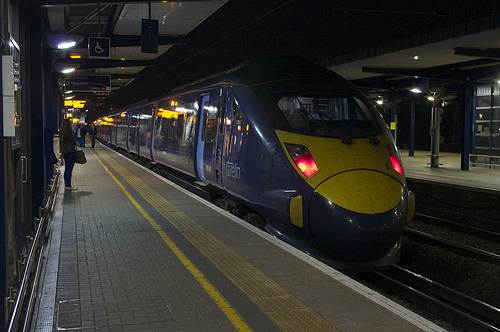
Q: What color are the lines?
A: Yellow.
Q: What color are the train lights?
A: Red.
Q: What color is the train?
A: Blue.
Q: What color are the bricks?
A: Gray.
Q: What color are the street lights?
A: White.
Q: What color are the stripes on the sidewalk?
A: Yellow.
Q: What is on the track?
A: A train.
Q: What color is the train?
A: Yellow and blue.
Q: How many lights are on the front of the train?
A: Two.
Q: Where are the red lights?
A: On the front of the train.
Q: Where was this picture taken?
A: A train station.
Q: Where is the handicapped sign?
A: Above the sidewalk.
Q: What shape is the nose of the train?
A: Curved.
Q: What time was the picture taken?
A: Night.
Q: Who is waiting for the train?
A: Passengers.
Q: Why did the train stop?
A: To get passengers.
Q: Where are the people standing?
A: On the platform.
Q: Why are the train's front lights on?
A: For the driver to see.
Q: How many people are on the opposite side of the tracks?
A: None.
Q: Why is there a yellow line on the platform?
A: For safety.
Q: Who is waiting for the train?
A: Passengers.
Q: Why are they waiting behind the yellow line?
A: For safety.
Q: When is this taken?
A: Night time.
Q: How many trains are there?
A: One.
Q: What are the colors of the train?
A: Yellow and blue.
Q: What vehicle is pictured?
A: A train.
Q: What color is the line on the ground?
A: Yellow.